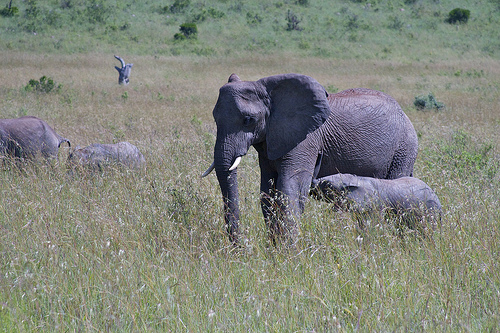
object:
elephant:
[198, 73, 421, 249]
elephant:
[308, 172, 446, 241]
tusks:
[228, 156, 241, 171]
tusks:
[201, 162, 216, 177]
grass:
[0, 0, 499, 333]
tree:
[112, 54, 133, 86]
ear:
[263, 72, 334, 160]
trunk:
[212, 154, 242, 245]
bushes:
[179, 22, 199, 39]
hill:
[141, 0, 305, 62]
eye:
[242, 117, 254, 126]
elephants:
[0, 114, 75, 177]